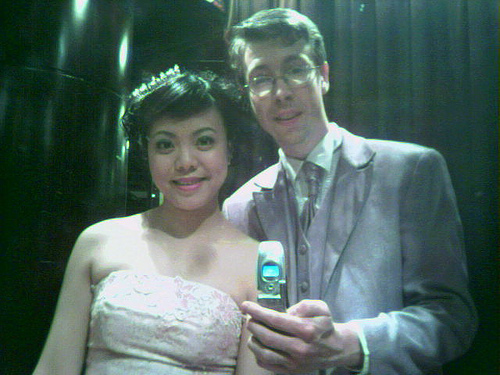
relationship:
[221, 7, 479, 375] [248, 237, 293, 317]
man holding cell phone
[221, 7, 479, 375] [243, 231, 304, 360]
man holding cell phone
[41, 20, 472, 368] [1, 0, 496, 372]
selfie in mirror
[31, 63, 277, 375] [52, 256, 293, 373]
people wearing dress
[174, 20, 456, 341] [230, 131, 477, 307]
man wearing coat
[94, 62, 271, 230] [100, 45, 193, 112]
head wearing crown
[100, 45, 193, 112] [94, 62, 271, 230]
crown on head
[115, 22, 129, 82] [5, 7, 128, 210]
light reflecting to wall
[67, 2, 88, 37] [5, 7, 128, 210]
light reflecting to wall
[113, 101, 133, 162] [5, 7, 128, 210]
light reflecting to wall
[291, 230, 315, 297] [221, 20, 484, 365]
buttons on coats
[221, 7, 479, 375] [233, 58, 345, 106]
man wearing glasses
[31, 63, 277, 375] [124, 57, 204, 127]
people wearing tiarra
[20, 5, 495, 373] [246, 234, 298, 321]
couple taking phone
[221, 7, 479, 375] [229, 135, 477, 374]
man wearing suit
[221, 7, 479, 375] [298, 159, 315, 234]
man wearing tie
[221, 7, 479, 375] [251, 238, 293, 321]
man holding cellphone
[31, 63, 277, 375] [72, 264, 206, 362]
people wearing dress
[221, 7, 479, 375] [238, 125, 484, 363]
man wearing suit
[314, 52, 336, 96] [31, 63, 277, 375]
ear on people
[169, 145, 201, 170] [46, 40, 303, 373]
nose on woman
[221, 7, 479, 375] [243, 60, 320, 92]
man wearing glasses